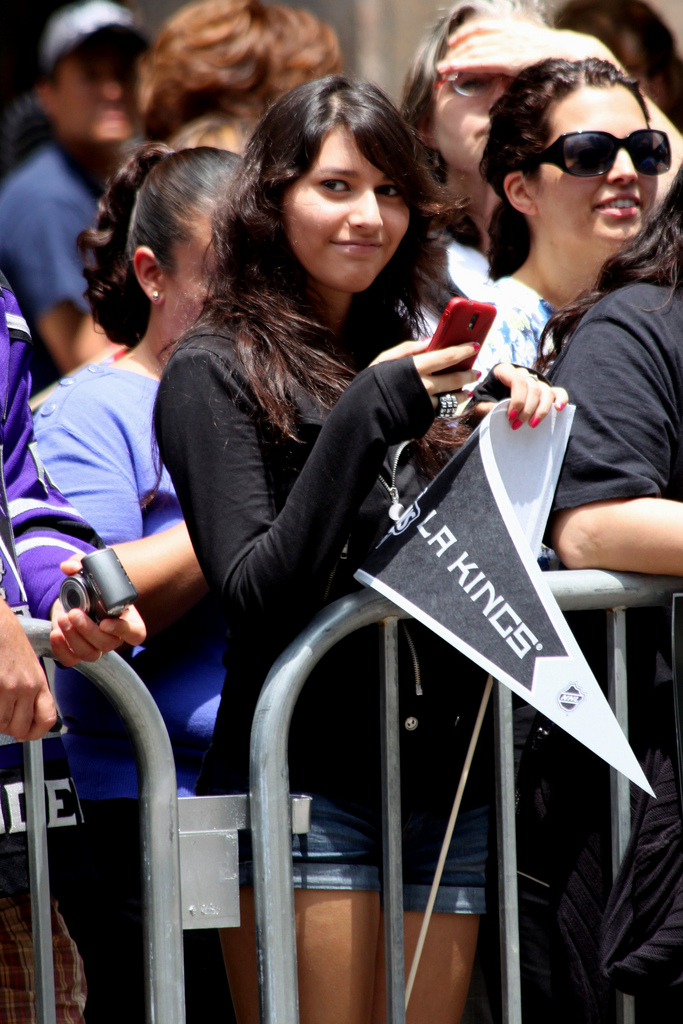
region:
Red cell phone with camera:
[409, 295, 500, 415]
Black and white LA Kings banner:
[329, 386, 663, 801]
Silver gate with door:
[0, 559, 680, 1016]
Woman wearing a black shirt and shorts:
[164, 74, 507, 1015]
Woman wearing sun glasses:
[440, 57, 681, 382]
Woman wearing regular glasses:
[382, 3, 586, 247]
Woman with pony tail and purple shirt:
[33, 134, 265, 1020]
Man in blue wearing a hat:
[8, 5, 159, 373]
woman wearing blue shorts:
[152, 72, 569, 1022]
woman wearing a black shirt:
[156, 77, 626, 1022]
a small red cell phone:
[423, 294, 503, 400]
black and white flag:
[343, 388, 659, 809]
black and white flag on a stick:
[357, 370, 655, 1018]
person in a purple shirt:
[1, 268, 145, 721]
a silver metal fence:
[0, 561, 679, 1022]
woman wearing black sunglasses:
[471, 59, 680, 300]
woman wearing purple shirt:
[27, 142, 237, 735]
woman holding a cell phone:
[144, 76, 590, 1020]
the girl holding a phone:
[154, 66, 573, 1022]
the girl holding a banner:
[146, 56, 587, 1021]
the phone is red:
[424, 294, 497, 378]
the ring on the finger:
[432, 392, 462, 421]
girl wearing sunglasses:
[463, 46, 680, 363]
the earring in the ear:
[148, 286, 163, 303]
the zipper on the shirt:
[376, 476, 403, 503]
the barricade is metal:
[209, 581, 678, 1022]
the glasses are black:
[509, 129, 671, 179]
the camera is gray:
[53, 548, 137, 626]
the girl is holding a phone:
[154, 73, 567, 1022]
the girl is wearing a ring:
[149, 73, 567, 1022]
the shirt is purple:
[29, 358, 229, 800]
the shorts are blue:
[206, 777, 487, 915]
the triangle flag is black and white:
[352, 404, 657, 799]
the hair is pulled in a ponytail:
[74, 140, 245, 350]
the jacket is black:
[155, 317, 552, 800]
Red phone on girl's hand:
[420, 282, 500, 387]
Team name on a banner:
[370, 463, 548, 663]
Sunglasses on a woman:
[543, 119, 681, 186]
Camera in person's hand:
[48, 560, 139, 621]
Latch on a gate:
[170, 784, 314, 938]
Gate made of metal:
[245, 609, 678, 1006]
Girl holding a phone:
[192, 51, 501, 547]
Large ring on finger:
[433, 390, 462, 428]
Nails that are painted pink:
[503, 405, 525, 435]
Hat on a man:
[30, 3, 148, 68]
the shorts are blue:
[203, 769, 483, 917]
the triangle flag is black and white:
[351, 403, 654, 803]